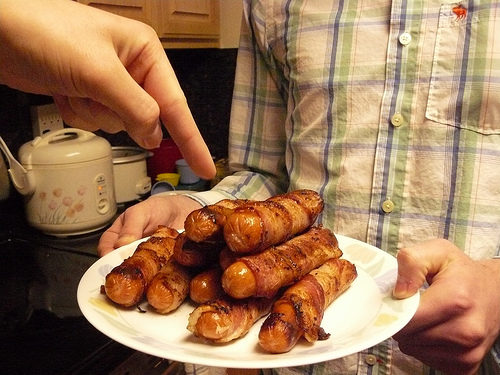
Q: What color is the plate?
A: White.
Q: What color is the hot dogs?
A: Brown.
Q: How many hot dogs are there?
A: 10.